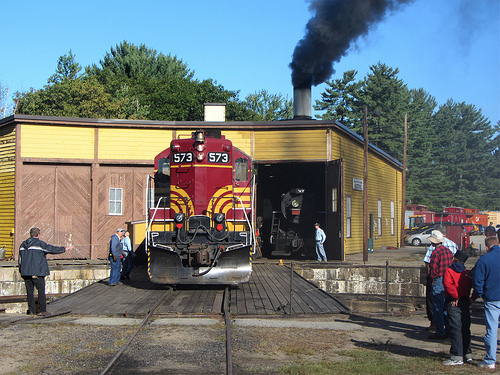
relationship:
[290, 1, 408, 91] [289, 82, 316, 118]
smoke coming out of stack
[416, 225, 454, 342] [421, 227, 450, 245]
man wearing a hat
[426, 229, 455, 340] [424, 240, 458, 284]
man wearing shirt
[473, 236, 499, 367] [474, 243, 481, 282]
man in shirt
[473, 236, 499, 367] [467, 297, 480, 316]
man in jeans